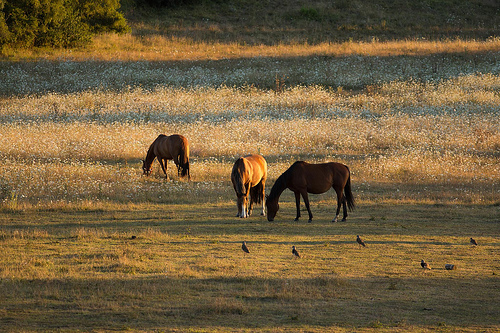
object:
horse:
[137, 133, 190, 183]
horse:
[229, 154, 269, 219]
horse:
[261, 160, 356, 225]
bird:
[239, 239, 251, 255]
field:
[0, 37, 498, 333]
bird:
[289, 245, 303, 260]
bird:
[352, 234, 367, 248]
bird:
[465, 236, 479, 247]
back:
[241, 154, 266, 165]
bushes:
[0, 0, 40, 50]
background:
[0, 0, 499, 49]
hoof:
[331, 213, 340, 222]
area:
[110, 34, 499, 54]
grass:
[436, 175, 481, 200]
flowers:
[15, 124, 41, 148]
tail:
[347, 166, 355, 209]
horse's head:
[263, 197, 279, 222]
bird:
[418, 258, 433, 271]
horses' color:
[291, 165, 327, 191]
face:
[237, 202, 248, 218]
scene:
[1, 0, 499, 332]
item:
[443, 263, 458, 272]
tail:
[182, 140, 190, 183]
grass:
[368, 156, 408, 185]